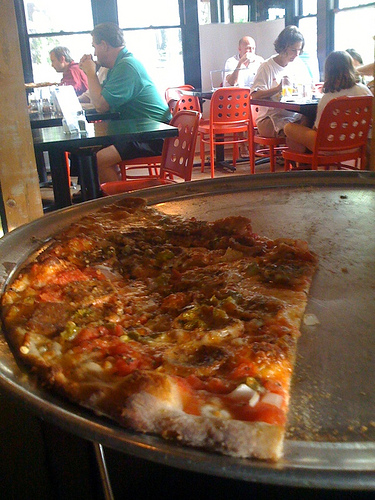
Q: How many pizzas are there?
A: One.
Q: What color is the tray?
A: Silver.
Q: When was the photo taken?
A: Daytime.